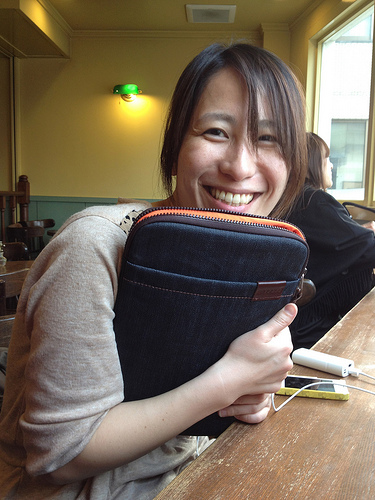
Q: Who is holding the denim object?
A: Woman.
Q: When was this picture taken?
A: Daytime.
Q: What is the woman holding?
A: Tablet case.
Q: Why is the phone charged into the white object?
A: Charging.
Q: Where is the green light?
A: On the wall.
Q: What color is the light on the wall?
A: Green.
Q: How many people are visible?
A: 2.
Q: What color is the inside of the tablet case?
A: Orange.